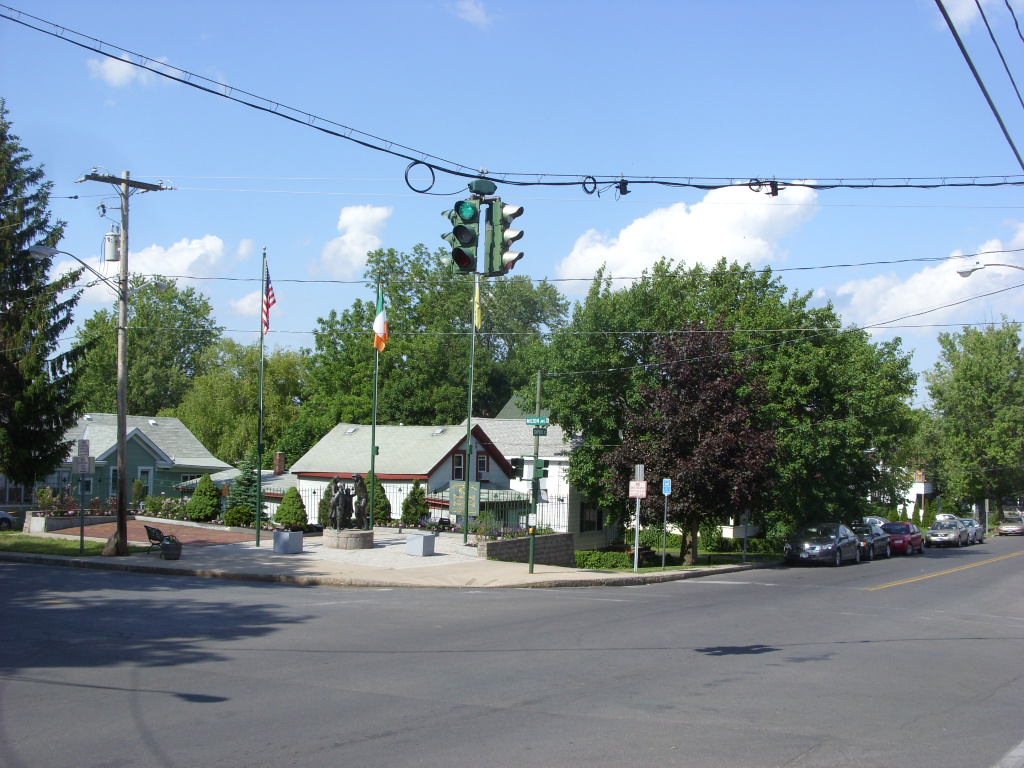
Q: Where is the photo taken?
A: At a traffic light.